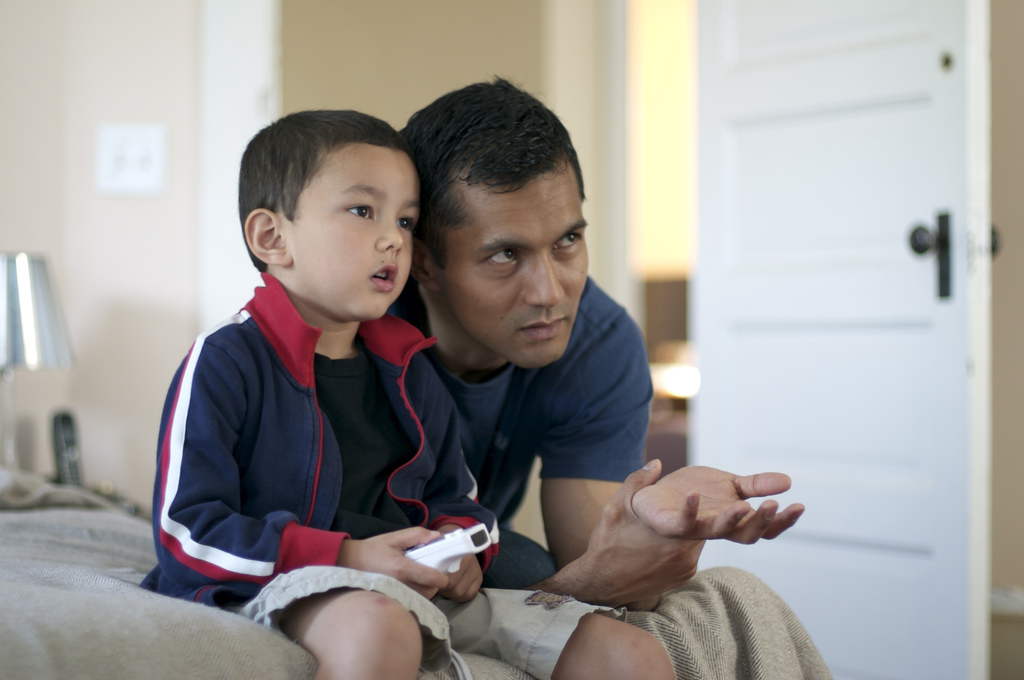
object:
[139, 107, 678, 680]
boy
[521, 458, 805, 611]
hands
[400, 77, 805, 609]
dad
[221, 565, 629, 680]
shorts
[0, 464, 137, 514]
table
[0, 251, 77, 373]
lamp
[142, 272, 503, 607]
jacket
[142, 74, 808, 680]
two guys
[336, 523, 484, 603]
boy's hands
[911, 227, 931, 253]
black-door knob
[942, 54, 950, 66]
black spot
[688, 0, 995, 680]
door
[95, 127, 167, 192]
white-light switch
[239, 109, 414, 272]
hair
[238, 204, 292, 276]
young-child ear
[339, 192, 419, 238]
young-child eyes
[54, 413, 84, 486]
black/grey phone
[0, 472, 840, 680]
beige bed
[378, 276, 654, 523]
blue shirt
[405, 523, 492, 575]
controller